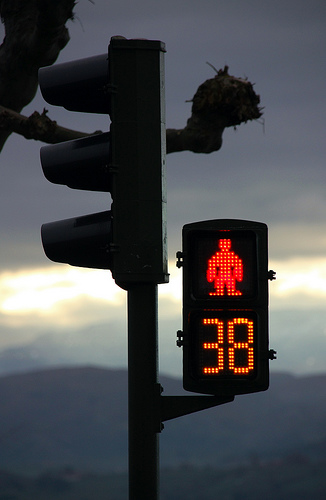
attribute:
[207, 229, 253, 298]
symbol — red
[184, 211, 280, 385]
light — black, rectangle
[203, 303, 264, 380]
number — orange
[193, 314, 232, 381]
number — three, orange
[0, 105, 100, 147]
stick — brown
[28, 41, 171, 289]
light — black, rectangle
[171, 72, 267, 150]
stick — brown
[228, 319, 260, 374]
number — eight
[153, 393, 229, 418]
pole — black, metal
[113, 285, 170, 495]
pole — black, metal, round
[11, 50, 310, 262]
sky — blue, dark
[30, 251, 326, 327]
clouds — white, low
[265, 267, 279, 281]
knob — black, round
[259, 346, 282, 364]
knob — black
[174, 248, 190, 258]
knob — black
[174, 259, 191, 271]
knob — black, round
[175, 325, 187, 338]
knob — black, round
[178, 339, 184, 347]
knob — black, round